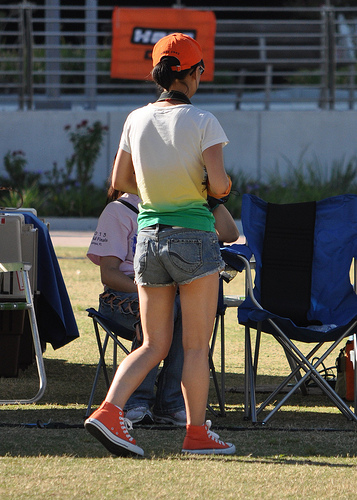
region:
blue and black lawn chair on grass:
[237, 185, 354, 433]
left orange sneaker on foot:
[88, 395, 152, 460]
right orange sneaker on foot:
[176, 412, 237, 465]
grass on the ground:
[38, 460, 126, 498]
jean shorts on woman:
[134, 216, 236, 283]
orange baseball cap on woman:
[147, 31, 203, 66]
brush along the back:
[8, 124, 103, 209]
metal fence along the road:
[228, 10, 325, 104]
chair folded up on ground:
[4, 205, 57, 417]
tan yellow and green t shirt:
[113, 91, 223, 232]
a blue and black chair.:
[218, 186, 354, 428]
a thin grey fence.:
[250, 7, 350, 99]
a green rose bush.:
[54, 114, 109, 192]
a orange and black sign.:
[113, 15, 213, 37]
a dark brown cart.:
[0, 296, 32, 381]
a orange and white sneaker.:
[171, 417, 239, 459]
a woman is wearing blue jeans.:
[95, 295, 138, 326]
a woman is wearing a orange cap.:
[147, 29, 207, 73]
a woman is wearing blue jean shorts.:
[124, 226, 226, 287]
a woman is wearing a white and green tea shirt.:
[146, 132, 187, 191]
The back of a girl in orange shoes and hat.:
[84, 33, 238, 455]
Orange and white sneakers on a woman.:
[81, 402, 236, 457]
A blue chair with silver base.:
[219, 192, 355, 426]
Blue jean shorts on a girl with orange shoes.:
[134, 220, 222, 285]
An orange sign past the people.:
[111, 5, 215, 83]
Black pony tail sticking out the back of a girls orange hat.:
[152, 59, 176, 93]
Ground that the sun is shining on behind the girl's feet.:
[1, 455, 355, 498]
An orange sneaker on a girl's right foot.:
[181, 423, 236, 454]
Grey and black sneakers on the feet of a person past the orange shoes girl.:
[122, 406, 210, 427]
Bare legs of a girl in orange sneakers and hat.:
[104, 267, 220, 425]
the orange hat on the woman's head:
[152, 32, 205, 70]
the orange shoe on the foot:
[181, 418, 235, 455]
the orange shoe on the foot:
[83, 400, 144, 457]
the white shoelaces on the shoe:
[205, 418, 225, 445]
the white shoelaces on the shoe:
[119, 410, 135, 440]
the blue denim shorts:
[132, 227, 225, 288]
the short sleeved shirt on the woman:
[116, 101, 230, 233]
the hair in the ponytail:
[150, 58, 173, 89]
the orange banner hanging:
[109, 6, 216, 83]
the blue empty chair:
[220, 187, 356, 425]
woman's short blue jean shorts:
[128, 217, 228, 293]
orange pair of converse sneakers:
[77, 398, 243, 463]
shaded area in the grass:
[0, 349, 356, 469]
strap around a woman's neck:
[156, 86, 195, 106]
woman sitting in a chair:
[90, 146, 216, 431]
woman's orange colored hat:
[148, 31, 210, 80]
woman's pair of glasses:
[187, 62, 205, 74]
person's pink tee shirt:
[80, 184, 163, 293]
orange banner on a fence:
[105, 4, 218, 90]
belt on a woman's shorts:
[137, 222, 173, 232]